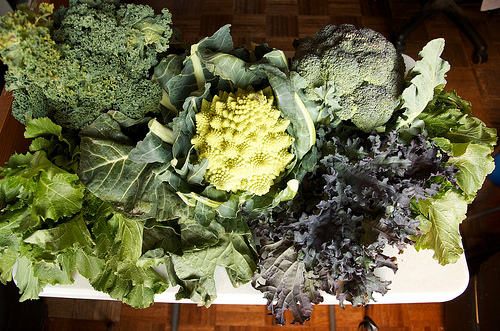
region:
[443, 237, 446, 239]
part of a vegetable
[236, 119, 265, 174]
inside of a brocholli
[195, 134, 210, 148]
part of a brocholli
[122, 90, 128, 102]
green part of a brocholli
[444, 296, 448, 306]
part of a table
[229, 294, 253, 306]
edge of a table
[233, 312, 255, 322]
part of the floor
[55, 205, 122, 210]
section of a leaf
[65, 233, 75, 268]
leaf of a vegetable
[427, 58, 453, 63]
outside of the leaf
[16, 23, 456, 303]
green vegetables on small white table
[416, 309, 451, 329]
floor is wooden and brown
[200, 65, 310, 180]
yellow vegetable in center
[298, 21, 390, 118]
green broccoli left of yellow vegetable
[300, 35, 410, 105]
green greens on left of yellow vegetable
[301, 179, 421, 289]
dark green leafy vegetable under yellow vegetable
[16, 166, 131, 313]
light green vegetable on lower left of yellow vegetable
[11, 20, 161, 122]
crinkly green vegetable upper left of yellow vegetable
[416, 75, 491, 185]
loose leaf green vegetable under broccoli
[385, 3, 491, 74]
black legs of chair in upper right corner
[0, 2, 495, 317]
leafy vegetables on a table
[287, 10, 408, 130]
head of broccoli is green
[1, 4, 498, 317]
the leafy vegetables are green purple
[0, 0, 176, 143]
leaves of kale are green and yellow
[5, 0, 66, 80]
part of leaves of kale that are dry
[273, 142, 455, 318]
leaves of vegetal that are purple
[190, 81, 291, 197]
type of cabbage color light green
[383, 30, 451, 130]
big leaf of broccoli is green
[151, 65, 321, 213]
cabbage surrounded by green leaves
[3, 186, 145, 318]
leaves of spinach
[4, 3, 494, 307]
Vegetables on a white tray.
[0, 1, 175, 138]
Green broccoli on a plate.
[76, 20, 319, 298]
White broccoli on a tray.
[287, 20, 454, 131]
Green broccoli on a tray.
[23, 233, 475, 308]
A white tray with vegetables on it.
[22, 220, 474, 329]
A white tray on top of a brown table.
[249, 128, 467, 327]
Red cabbage on a white tray.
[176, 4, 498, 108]
The floor is wooden tiled.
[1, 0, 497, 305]
A variety of vegetables on a plate.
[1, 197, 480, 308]
A tray with a variety of vegetables on top of a table.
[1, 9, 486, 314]
vegetables laying on a white board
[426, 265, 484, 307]
rounded edge of the white board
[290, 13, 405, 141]
head of green broccoli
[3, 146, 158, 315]
bunch of green leaves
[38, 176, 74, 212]
thin line running along the leaf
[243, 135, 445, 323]
purpleish leaves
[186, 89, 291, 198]
textured yellow vegetable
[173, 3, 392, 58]
brown wooden tiling on the floor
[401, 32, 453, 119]
light shining on the leaf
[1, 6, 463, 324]
group of vegetables